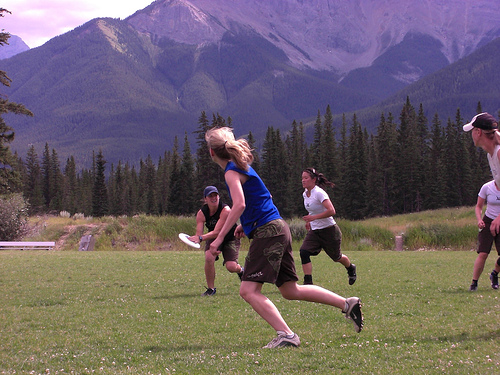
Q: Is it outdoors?
A: Yes, it is outdoors.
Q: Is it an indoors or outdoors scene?
A: It is outdoors.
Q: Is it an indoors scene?
A: No, it is outdoors.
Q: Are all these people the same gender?
A: Yes, all the people are female.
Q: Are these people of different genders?
A: No, all the people are female.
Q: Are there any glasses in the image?
A: No, there are no glasses.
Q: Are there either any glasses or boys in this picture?
A: No, there are no glasses or boys.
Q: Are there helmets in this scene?
A: No, there are no helmets.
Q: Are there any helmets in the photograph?
A: No, there are no helmets.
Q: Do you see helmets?
A: No, there are no helmets.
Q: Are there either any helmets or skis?
A: No, there are no helmets or skis.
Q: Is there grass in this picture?
A: Yes, there is grass.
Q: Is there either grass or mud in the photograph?
A: Yes, there is grass.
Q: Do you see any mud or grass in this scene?
A: Yes, there is grass.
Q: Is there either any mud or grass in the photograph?
A: Yes, there is grass.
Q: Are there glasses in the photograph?
A: No, there are no glasses.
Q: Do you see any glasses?
A: No, there are no glasses.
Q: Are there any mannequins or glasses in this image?
A: No, there are no glasses or mannequins.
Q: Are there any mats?
A: No, there are no mats.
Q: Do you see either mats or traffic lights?
A: No, there are no mats or traffic lights.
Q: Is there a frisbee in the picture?
A: Yes, there is a frisbee.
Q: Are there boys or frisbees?
A: Yes, there is a frisbee.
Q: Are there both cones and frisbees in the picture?
A: No, there is a frisbee but no cones.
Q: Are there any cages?
A: No, there are no cages.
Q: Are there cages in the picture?
A: No, there are no cages.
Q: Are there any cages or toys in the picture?
A: No, there are no cages or toys.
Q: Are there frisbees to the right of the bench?
A: Yes, there is a frisbee to the right of the bench.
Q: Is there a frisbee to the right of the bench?
A: Yes, there is a frisbee to the right of the bench.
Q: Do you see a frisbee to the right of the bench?
A: Yes, there is a frisbee to the right of the bench.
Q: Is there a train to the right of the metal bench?
A: No, there is a frisbee to the right of the bench.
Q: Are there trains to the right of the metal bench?
A: No, there is a frisbee to the right of the bench.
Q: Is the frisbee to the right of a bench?
A: Yes, the frisbee is to the right of a bench.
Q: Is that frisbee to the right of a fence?
A: No, the frisbee is to the right of a bench.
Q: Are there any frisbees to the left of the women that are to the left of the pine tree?
A: Yes, there is a frisbee to the left of the women.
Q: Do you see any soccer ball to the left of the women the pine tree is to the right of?
A: No, there is a frisbee to the left of the women.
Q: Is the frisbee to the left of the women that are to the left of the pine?
A: Yes, the frisbee is to the left of the women.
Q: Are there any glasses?
A: No, there are no glasses.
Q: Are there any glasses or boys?
A: No, there are no glasses or boys.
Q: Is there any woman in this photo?
A: Yes, there is a woman.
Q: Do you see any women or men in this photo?
A: Yes, there is a woman.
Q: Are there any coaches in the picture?
A: No, there are no coaches.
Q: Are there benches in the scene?
A: Yes, there is a bench.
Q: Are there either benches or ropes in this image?
A: Yes, there is a bench.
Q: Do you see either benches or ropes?
A: Yes, there is a bench.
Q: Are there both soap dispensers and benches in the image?
A: No, there is a bench but no soap dispensers.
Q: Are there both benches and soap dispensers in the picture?
A: No, there is a bench but no soap dispensers.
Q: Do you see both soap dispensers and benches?
A: No, there is a bench but no soap dispensers.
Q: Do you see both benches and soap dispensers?
A: No, there is a bench but no soap dispensers.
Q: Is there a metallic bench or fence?
A: Yes, there is a metal bench.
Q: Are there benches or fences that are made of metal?
A: Yes, the bench is made of metal.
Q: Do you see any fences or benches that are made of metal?
A: Yes, the bench is made of metal.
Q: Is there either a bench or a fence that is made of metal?
A: Yes, the bench is made of metal.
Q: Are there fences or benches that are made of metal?
A: Yes, the bench is made of metal.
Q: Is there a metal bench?
A: Yes, there is a bench that is made of metal.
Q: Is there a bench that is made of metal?
A: Yes, there is a bench that is made of metal.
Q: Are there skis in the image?
A: No, there are no skis.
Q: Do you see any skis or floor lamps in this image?
A: No, there are no skis or floor lamps.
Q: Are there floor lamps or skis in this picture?
A: No, there are no skis or floor lamps.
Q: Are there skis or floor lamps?
A: No, there are no skis or floor lamps.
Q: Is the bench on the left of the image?
A: Yes, the bench is on the left of the image.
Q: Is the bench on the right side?
A: No, the bench is on the left of the image.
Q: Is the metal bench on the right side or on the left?
A: The bench is on the left of the image.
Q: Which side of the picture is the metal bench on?
A: The bench is on the left of the image.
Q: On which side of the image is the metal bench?
A: The bench is on the left of the image.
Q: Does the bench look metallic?
A: Yes, the bench is metallic.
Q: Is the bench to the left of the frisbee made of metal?
A: Yes, the bench is made of metal.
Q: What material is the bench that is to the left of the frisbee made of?
A: The bench is made of metal.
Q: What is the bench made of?
A: The bench is made of metal.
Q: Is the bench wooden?
A: No, the bench is metallic.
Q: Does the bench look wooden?
A: No, the bench is metallic.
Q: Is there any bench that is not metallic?
A: No, there is a bench but it is metallic.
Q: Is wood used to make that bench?
A: No, the bench is made of metal.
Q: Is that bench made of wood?
A: No, the bench is made of metal.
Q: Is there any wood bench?
A: No, there is a bench but it is made of metal.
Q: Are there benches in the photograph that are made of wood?
A: No, there is a bench but it is made of metal.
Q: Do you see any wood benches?
A: No, there is a bench but it is made of metal.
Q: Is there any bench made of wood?
A: No, there is a bench but it is made of metal.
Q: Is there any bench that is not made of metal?
A: No, there is a bench but it is made of metal.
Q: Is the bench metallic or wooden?
A: The bench is metallic.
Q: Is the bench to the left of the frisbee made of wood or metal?
A: The bench is made of metal.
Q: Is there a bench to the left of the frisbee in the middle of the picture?
A: Yes, there is a bench to the left of the frisbee.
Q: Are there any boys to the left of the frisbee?
A: No, there is a bench to the left of the frisbee.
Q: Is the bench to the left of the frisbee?
A: Yes, the bench is to the left of the frisbee.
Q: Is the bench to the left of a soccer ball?
A: No, the bench is to the left of the frisbee.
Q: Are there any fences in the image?
A: No, there are no fences.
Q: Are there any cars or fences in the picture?
A: No, there are no fences or cars.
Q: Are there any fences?
A: No, there are no fences.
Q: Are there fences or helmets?
A: No, there are no fences or helmets.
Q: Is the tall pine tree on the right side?
A: Yes, the pine tree is on the right of the image.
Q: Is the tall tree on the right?
A: Yes, the pine tree is on the right of the image.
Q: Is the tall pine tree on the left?
A: No, the pine tree is on the right of the image.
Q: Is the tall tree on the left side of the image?
A: No, the pine tree is on the right of the image.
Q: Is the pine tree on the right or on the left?
A: The pine tree is on the right of the image.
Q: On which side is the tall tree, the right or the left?
A: The pine tree is on the right of the image.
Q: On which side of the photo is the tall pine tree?
A: The pine is on the right of the image.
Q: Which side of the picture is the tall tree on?
A: The pine is on the right of the image.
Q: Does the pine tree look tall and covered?
A: Yes, the pine tree is tall and covered.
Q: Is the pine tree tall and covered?
A: Yes, the pine tree is tall and covered.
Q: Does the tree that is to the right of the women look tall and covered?
A: Yes, the pine tree is tall and covered.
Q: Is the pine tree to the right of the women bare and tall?
A: No, the pine is tall but covered.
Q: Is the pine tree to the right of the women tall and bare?
A: No, the pine is tall but covered.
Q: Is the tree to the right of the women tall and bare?
A: No, the pine is tall but covered.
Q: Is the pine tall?
A: Yes, the pine is tall.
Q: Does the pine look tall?
A: Yes, the pine is tall.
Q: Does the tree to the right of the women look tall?
A: Yes, the pine is tall.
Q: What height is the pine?
A: The pine is tall.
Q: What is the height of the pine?
A: The pine is tall.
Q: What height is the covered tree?
A: The pine is tall.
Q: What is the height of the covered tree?
A: The pine is tall.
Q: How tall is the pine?
A: The pine is tall.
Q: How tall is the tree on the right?
A: The pine is tall.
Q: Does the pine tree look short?
A: No, the pine tree is tall.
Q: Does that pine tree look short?
A: No, the pine tree is tall.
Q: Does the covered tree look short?
A: No, the pine tree is tall.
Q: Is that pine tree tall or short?
A: The pine tree is tall.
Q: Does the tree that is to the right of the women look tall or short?
A: The pine tree is tall.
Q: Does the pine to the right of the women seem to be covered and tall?
A: Yes, the pine tree is covered and tall.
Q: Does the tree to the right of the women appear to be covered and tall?
A: Yes, the pine tree is covered and tall.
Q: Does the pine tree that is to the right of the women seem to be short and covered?
A: No, the pine tree is covered but tall.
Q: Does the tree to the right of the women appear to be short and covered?
A: No, the pine tree is covered but tall.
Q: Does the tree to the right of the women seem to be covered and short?
A: No, the pine tree is covered but tall.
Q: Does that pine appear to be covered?
A: Yes, the pine is covered.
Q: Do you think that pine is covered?
A: Yes, the pine is covered.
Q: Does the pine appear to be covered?
A: Yes, the pine is covered.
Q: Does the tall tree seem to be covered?
A: Yes, the pine is covered.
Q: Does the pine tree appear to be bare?
A: No, the pine tree is covered.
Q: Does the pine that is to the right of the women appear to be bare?
A: No, the pine tree is covered.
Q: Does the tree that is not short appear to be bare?
A: No, the pine tree is covered.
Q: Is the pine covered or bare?
A: The pine is covered.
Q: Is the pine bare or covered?
A: The pine is covered.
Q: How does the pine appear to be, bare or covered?
A: The pine is covered.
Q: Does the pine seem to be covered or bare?
A: The pine is covered.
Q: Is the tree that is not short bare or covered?
A: The pine is covered.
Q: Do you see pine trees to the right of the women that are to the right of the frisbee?
A: Yes, there is a pine tree to the right of the women.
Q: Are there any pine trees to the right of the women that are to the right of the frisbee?
A: Yes, there is a pine tree to the right of the women.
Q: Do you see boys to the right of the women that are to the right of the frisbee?
A: No, there is a pine tree to the right of the women.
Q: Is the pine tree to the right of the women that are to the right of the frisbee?
A: Yes, the pine tree is to the right of the women.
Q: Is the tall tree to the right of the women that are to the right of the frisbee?
A: Yes, the pine tree is to the right of the women.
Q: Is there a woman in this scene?
A: Yes, there are women.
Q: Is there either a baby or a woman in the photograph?
A: Yes, there are women.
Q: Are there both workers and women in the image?
A: No, there are women but no workers.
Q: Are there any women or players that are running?
A: Yes, the women are running.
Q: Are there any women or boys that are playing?
A: Yes, the women are playing.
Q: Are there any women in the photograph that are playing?
A: Yes, there are women that are playing.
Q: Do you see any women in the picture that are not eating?
A: Yes, there are women that are playing .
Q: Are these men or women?
A: These are women.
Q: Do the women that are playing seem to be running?
A: Yes, the women are running.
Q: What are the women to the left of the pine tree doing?
A: The women are running.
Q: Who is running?
A: The women are running.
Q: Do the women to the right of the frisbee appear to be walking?
A: No, the women are running.